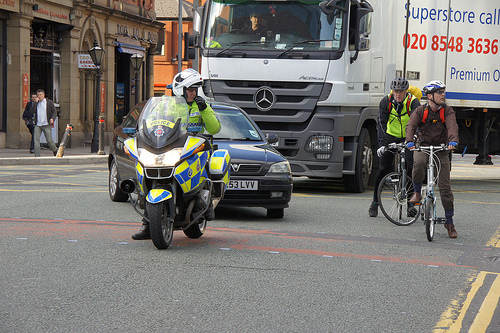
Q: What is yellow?
A: Lines on the street.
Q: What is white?
A: Truck.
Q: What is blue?
A: Car.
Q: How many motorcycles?
A: One.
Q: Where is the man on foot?
A: Sidewalk.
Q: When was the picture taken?
A: Daytime.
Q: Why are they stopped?
A: Traffic.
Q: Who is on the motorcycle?
A: Police.